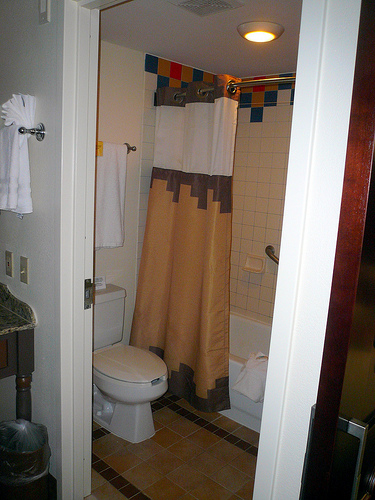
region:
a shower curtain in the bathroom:
[133, 78, 230, 408]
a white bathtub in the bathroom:
[208, 307, 272, 419]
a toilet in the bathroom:
[94, 279, 167, 446]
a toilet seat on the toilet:
[91, 340, 166, 381]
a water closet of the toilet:
[94, 279, 124, 343]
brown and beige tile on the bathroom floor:
[85, 387, 257, 496]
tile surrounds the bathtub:
[136, 55, 295, 322]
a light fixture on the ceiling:
[231, 15, 283, 46]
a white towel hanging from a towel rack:
[97, 138, 134, 243]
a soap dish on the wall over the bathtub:
[241, 250, 266, 276]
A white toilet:
[78, 283, 171, 444]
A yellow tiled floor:
[146, 448, 219, 493]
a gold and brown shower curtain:
[119, 73, 244, 411]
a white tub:
[129, 310, 273, 419]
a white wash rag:
[230, 350, 273, 401]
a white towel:
[1, 91, 39, 211]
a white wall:
[104, 72, 132, 112]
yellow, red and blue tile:
[239, 83, 279, 119]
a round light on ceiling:
[235, 18, 282, 41]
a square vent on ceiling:
[174, 0, 234, 18]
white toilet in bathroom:
[92, 268, 168, 453]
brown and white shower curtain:
[139, 71, 239, 414]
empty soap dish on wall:
[237, 247, 270, 282]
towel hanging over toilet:
[93, 133, 130, 253]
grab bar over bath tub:
[259, 240, 279, 268]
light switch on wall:
[15, 249, 35, 295]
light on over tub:
[233, 11, 289, 46]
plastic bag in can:
[2, 416, 55, 498]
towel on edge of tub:
[225, 342, 270, 406]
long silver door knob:
[336, 416, 371, 499]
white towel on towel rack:
[92, 121, 133, 265]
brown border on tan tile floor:
[169, 419, 252, 476]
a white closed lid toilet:
[85, 279, 169, 456]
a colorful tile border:
[145, 50, 289, 119]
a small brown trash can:
[2, 413, 63, 497]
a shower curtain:
[137, 75, 232, 352]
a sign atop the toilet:
[83, 267, 120, 300]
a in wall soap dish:
[237, 239, 285, 281]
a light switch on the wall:
[12, 256, 42, 306]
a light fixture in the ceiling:
[225, 22, 290, 63]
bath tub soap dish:
[237, 249, 264, 275]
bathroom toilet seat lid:
[86, 339, 176, 390]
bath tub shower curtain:
[129, 75, 241, 416]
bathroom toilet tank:
[92, 273, 139, 344]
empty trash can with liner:
[0, 416, 55, 495]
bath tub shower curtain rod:
[149, 70, 294, 96]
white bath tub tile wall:
[234, 124, 274, 316]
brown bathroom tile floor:
[163, 424, 239, 494]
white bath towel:
[99, 156, 131, 251]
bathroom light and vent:
[178, 1, 291, 55]